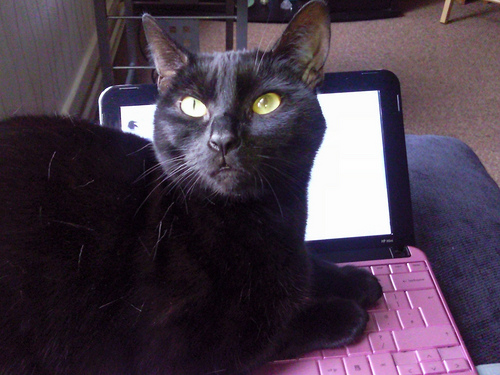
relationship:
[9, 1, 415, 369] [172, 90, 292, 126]
cat has eyes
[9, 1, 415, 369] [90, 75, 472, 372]
cat on computer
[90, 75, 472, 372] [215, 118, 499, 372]
computer on chair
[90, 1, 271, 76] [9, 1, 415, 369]
metal behind cat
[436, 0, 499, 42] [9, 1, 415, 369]
wood behind cat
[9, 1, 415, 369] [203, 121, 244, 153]
cat has nose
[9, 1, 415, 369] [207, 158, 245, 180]
cat has mouth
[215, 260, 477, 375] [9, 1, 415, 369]
keyboard underneath cat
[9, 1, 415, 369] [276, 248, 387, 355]
cat has legs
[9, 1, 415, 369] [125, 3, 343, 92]
cat has ears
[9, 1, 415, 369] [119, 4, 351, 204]
cat has head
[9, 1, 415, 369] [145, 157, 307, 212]
cat has whiskers